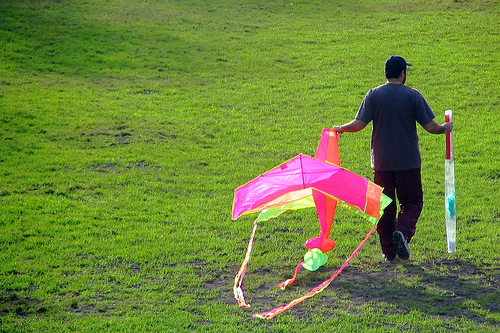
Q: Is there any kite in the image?
A: Yes, there is a kite.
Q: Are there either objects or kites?
A: Yes, there is a kite.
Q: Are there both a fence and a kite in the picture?
A: No, there is a kite but no fences.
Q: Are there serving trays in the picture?
A: No, there are no serving trays.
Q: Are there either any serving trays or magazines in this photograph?
A: No, there are no serving trays or magazines.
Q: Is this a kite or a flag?
A: This is a kite.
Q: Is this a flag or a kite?
A: This is a kite.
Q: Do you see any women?
A: No, there are no women.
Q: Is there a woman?
A: No, there are no women.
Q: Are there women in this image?
A: No, there are no women.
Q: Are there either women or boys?
A: No, there are no women or boys.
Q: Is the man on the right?
A: Yes, the man is on the right of the image.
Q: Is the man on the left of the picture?
A: No, the man is on the right of the image.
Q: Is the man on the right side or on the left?
A: The man is on the right of the image.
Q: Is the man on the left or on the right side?
A: The man is on the right of the image.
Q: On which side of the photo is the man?
A: The man is on the right of the image.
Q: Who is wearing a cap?
A: The man is wearing a cap.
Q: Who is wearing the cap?
A: The man is wearing a cap.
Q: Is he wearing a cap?
A: Yes, the man is wearing a cap.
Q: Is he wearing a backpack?
A: No, the man is wearing a cap.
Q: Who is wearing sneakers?
A: The man is wearing sneakers.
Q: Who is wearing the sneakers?
A: The man is wearing sneakers.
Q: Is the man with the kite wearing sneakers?
A: Yes, the man is wearing sneakers.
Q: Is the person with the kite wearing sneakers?
A: Yes, the man is wearing sneakers.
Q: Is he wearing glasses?
A: No, the man is wearing sneakers.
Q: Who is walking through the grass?
A: The man is walking through the grass.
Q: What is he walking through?
A: The man is walking through the grass.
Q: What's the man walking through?
A: The man is walking through the grass.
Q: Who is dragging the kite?
A: The man is dragging the kite.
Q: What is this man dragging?
A: The man is dragging the kite.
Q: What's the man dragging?
A: The man is dragging the kite.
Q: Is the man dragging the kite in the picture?
A: Yes, the man is dragging the kite.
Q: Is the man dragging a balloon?
A: No, the man is dragging the kite.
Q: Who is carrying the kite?
A: The man is carrying the kite.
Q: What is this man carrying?
A: The man is carrying a kite.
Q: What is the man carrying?
A: The man is carrying a kite.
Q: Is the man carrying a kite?
A: Yes, the man is carrying a kite.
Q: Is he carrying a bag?
A: No, the man is carrying a kite.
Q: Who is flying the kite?
A: The man is flying the kite.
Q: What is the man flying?
A: The man is flying the kite.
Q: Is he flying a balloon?
A: No, the man is flying the kite.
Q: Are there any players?
A: No, there are no players.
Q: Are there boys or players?
A: No, there are no players or boys.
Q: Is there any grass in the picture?
A: Yes, there is grass.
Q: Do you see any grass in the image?
A: Yes, there is grass.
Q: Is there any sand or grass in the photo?
A: Yes, there is grass.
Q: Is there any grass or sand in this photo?
A: Yes, there is grass.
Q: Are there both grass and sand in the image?
A: No, there is grass but no sand.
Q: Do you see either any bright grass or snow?
A: Yes, there is bright grass.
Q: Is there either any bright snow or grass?
A: Yes, there is bright grass.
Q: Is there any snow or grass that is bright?
A: Yes, the grass is bright.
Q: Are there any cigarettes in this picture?
A: No, there are no cigarettes.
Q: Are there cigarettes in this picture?
A: No, there are no cigarettes.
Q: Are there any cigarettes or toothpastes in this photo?
A: No, there are no cigarettes or toothpastes.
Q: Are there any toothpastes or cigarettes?
A: No, there are no cigarettes or toothpastes.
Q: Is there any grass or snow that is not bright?
A: No, there is grass but it is bright.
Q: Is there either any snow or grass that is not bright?
A: No, there is grass but it is bright.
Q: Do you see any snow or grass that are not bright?
A: No, there is grass but it is bright.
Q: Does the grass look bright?
A: Yes, the grass is bright.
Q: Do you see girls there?
A: No, there are no girls.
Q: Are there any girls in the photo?
A: No, there are no girls.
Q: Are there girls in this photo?
A: No, there are no girls.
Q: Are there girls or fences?
A: No, there are no girls or fences.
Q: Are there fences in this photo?
A: No, there are no fences.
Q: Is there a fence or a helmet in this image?
A: No, there are no fences or helmets.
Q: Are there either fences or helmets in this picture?
A: No, there are no fences or helmets.